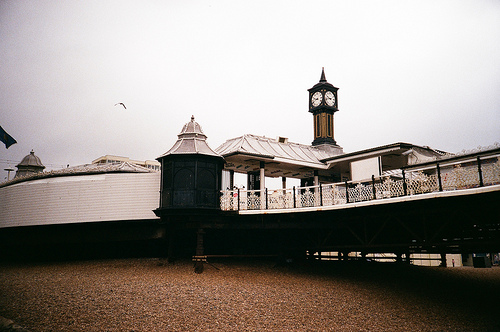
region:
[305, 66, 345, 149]
A tall clock tower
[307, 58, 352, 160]
The clock tower is brown and black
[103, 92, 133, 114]
A bird flies over the building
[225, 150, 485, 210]
The fence has black posts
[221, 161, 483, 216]
White chain link fence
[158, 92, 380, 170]
The roof of the building is white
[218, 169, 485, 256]
A long black bridge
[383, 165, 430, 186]
A striped canopy near the building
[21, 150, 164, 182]
Buildings behind the wall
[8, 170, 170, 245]
White brick wall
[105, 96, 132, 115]
bird flying in the sky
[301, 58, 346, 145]
small clock tower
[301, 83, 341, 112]
two clocks on either side of the tower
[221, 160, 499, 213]
short, white chain link fence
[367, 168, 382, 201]
short black pole on the fence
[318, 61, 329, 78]
pointed tip of the clock tower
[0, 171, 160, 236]
curved white brick wall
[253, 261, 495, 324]
shadows on the ground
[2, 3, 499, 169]
gray sky coverd in clouds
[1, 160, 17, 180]
powerlines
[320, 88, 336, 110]
clock in clock tower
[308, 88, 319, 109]
clock in clock tower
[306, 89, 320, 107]
black and white clock in clock tower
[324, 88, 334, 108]
black and white clock in clock tower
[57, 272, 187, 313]
tan and gray gravel on ground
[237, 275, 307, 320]
tan and gray gravel on ground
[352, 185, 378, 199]
white fencing on walkway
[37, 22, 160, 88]
gray and white clouds in sky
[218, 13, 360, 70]
gray and white clouds in sky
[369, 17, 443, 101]
gray and white clouds in sky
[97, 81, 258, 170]
the sky is clear and visible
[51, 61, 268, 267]
the sky is clear and visible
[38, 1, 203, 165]
the sky is clear and visible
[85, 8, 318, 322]
the sky is clear and visible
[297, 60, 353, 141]
clock tower near a pavillion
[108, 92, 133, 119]
bird in the sky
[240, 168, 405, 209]
white fence along edge of boardwalk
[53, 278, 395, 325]
brown sand on the ground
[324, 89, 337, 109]
clock on a tower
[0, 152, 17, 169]
electric wires in the background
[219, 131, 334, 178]
roof of a pavillion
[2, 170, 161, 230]
round building above the sand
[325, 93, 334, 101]
blakc hands on a clock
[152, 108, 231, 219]
ornate building above sand